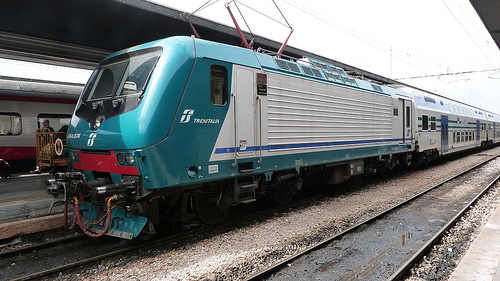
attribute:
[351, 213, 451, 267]
puddle — water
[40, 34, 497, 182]
train — blue and silver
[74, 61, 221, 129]
windshield — glass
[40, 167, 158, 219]
bumper — on the front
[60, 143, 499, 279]
rocks — small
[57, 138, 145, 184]
trim — red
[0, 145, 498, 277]
ground — wet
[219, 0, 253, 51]
frame — red